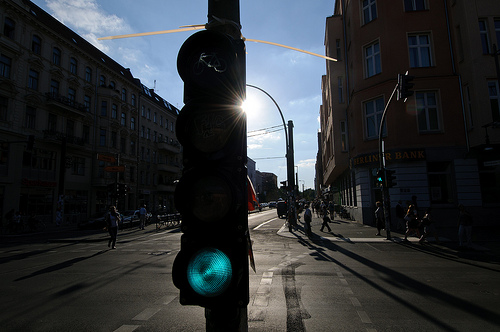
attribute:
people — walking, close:
[90, 193, 437, 265]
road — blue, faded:
[0, 164, 466, 328]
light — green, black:
[170, 16, 270, 331]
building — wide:
[1, 5, 204, 250]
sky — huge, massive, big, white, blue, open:
[39, 2, 357, 189]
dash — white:
[255, 213, 293, 247]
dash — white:
[242, 200, 292, 241]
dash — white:
[261, 200, 302, 276]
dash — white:
[244, 193, 293, 251]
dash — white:
[248, 206, 275, 242]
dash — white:
[244, 186, 296, 247]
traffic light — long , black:
[166, 28, 276, 329]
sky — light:
[90, 8, 357, 206]